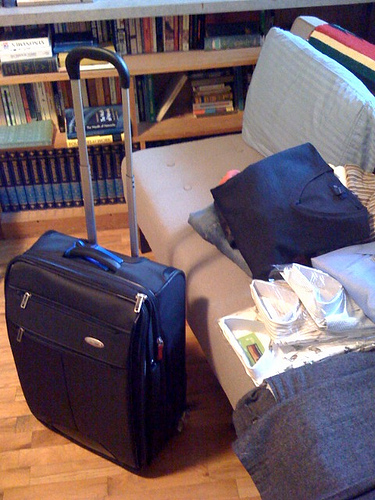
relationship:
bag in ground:
[4, 231, 186, 471] [2, 211, 271, 498]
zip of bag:
[129, 288, 148, 317] [0, 224, 192, 485]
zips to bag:
[4, 279, 38, 347] [4, 231, 186, 471]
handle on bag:
[62, 40, 139, 94] [4, 231, 186, 471]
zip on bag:
[129, 288, 148, 315] [4, 231, 186, 471]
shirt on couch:
[282, 264, 364, 336] [124, 10, 357, 497]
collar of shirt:
[218, 306, 284, 383] [211, 282, 332, 386]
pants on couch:
[223, 344, 354, 498] [118, 11, 355, 460]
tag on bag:
[69, 237, 133, 272] [4, 231, 186, 471]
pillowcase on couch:
[183, 184, 265, 281] [118, 11, 355, 460]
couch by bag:
[118, 11, 355, 460] [4, 231, 186, 471]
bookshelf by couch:
[0, 2, 348, 230] [121, 11, 363, 420]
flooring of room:
[4, 434, 83, 498] [4, 0, 374, 497]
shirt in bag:
[286, 266, 363, 335] [270, 255, 325, 307]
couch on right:
[118, 16, 375, 460] [110, 3, 373, 498]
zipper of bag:
[16, 287, 108, 325] [4, 231, 186, 471]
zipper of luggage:
[13, 321, 64, 355] [9, 225, 184, 458]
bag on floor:
[4, 231, 186, 466] [17, 404, 85, 498]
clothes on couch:
[216, 156, 373, 478] [126, 30, 371, 497]